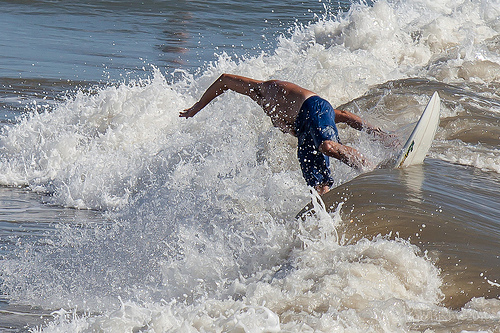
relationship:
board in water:
[393, 90, 440, 168] [0, 0, 500, 332]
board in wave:
[393, 90, 440, 168] [0, 0, 499, 330]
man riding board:
[177, 73, 402, 198] [393, 90, 440, 168]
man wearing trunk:
[177, 73, 402, 198] [293, 97, 338, 187]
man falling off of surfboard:
[177, 73, 402, 198] [393, 90, 448, 171]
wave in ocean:
[0, 0, 499, 330] [5, 5, 494, 330]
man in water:
[177, 73, 402, 198] [0, 0, 500, 332]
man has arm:
[177, 73, 402, 198] [189, 70, 263, 112]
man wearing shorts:
[177, 73, 402, 198] [286, 104, 346, 185]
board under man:
[390, 88, 447, 173] [174, 68, 412, 204]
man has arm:
[177, 73, 402, 198] [179, 73, 261, 119]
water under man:
[0, 2, 480, 152] [168, 60, 374, 192]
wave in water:
[0, 0, 499, 330] [0, 0, 500, 332]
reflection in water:
[331, 88, 454, 215] [0, 0, 500, 332]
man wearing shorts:
[177, 73, 402, 198] [290, 96, 332, 186]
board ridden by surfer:
[393, 90, 440, 168] [180, 68, 357, 185]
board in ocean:
[393, 90, 440, 168] [5, 5, 494, 330]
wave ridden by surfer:
[0, 0, 499, 330] [177, 72, 384, 198]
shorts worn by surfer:
[294, 96, 341, 190] [180, 72, 400, 194]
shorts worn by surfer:
[289, 99, 339, 192] [177, 72, 384, 198]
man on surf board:
[177, 73, 402, 198] [389, 90, 444, 170]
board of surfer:
[393, 90, 440, 168] [177, 68, 406, 207]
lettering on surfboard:
[401, 135, 418, 167] [388, 87, 445, 176]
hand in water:
[363, 126, 393, 140] [0, 0, 500, 332]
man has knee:
[172, 64, 394, 189] [316, 138, 338, 158]